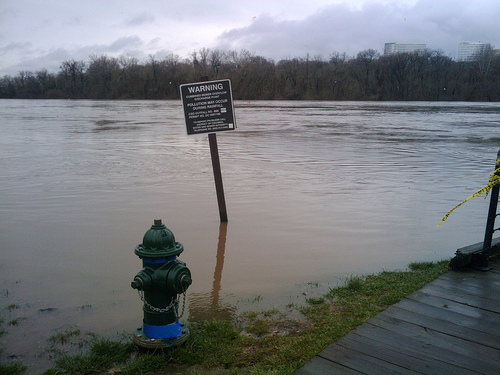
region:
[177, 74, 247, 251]
a warning sign protruding from water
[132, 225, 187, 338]
a green and blue fire hydrant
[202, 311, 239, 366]
an area of green grass next to the water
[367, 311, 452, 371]
a wet wooden deck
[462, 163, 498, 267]
yellow caution tap wrapped around a pole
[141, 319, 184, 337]
a blue band at the base of a hydrant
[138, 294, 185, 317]
a metal chain on a fire hydrant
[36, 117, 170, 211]
a brown lake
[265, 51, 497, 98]
an area of trees behind a lake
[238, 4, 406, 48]
dark rain clouds in the sky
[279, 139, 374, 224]
the water is not clear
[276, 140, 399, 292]
the water is not clear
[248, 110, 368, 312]
the water is not clear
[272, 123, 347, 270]
the water is not clear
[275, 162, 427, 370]
the water is not clear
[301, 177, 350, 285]
the water is not clear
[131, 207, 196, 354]
green fire hydrant with blue paint on bottom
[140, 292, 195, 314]
a silver chain hanging from fire hydrant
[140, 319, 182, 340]
a blue paint on green fire hydrant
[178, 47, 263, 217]
A black and white warning sign in water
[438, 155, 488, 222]
a yellow and black tape hanging from dock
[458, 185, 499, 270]
part of a railing on dock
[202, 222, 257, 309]
a reflection of sign in water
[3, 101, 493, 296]
muddy water in a huge lake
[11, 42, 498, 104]
many trees in background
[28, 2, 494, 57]
a cloudy blue skies in background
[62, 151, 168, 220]
the water is unclear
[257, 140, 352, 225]
the water is unclear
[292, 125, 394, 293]
the water is unclear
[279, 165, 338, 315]
the water is unclear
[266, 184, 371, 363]
the water is unclear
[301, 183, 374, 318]
the water is unclear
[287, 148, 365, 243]
the water is clear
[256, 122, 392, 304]
the water is clear